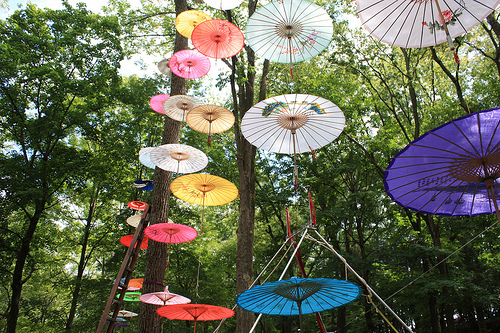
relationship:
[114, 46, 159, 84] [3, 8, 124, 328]
sunlight coming through trees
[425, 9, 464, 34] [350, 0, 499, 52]
rose on umbrella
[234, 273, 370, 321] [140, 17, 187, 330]
umbrella hanging from tree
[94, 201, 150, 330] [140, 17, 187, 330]
ladder against tree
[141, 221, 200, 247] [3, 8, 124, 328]
umbrella in trees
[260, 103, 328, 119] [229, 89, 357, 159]
dragon on parasol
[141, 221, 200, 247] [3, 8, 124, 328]
umbrella against trees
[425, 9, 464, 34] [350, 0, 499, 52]
flower on umbrella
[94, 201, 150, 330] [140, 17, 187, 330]
ladder leaning on tree